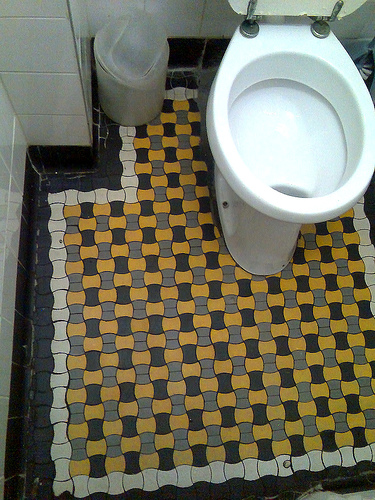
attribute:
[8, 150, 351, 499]
floor — black, yellow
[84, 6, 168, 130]
trash can — plastic, white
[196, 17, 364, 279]
toilet — white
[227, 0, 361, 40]
lid — white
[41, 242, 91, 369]
tiles — yellow, black, crocked, white, colored, gray, patterned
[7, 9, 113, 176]
wall — white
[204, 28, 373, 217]
seat — upturned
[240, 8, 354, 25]
hinges — silver, metal